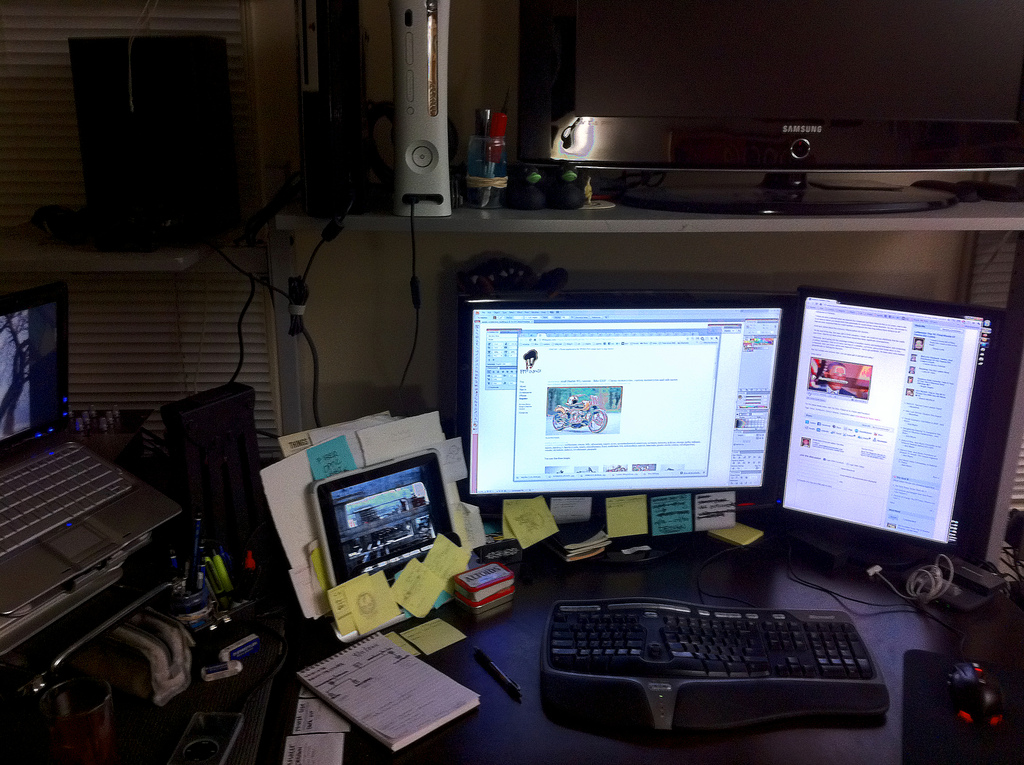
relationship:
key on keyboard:
[698, 616, 720, 632] [535, 594, 879, 703]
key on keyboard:
[618, 612, 642, 638] [538, 588, 880, 722]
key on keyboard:
[736, 635, 752, 655] [538, 588, 880, 722]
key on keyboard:
[762, 637, 795, 663] [538, 588, 880, 722]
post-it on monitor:
[335, 568, 400, 640] [300, 432, 473, 621]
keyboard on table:
[544, 603, 875, 683] [162, 514, 977, 746]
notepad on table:
[291, 633, 490, 735] [207, 532, 957, 746]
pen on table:
[464, 651, 545, 714] [207, 532, 957, 746]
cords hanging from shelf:
[173, 223, 362, 390] [30, 164, 357, 260]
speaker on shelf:
[354, 11, 542, 240] [356, 15, 519, 214]